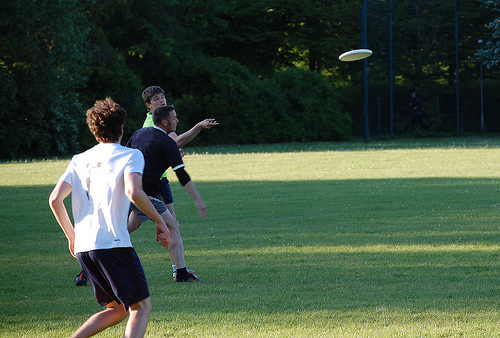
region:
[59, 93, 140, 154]
the head of a man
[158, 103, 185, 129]
the face of a man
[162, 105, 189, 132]
the nose of a man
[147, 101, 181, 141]
the ear of a man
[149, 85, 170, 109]
the eyes of a man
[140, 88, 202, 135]
the hair of a man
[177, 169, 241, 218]
the hand of a man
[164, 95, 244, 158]
the arm of a man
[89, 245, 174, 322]
the legs of a man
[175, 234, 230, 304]
the foot of a man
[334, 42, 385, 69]
A Frisbee flying through the air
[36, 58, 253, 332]
Grown men playing with a Frisbee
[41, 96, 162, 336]
A man in a white shirt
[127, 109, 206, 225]
A black man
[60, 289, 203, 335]
White legs of a man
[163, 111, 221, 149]
A man's arm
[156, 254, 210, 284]
A man's shoe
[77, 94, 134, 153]
Curly hair on the head of a man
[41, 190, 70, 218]
A man's left elbow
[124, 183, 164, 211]
A man's right elbow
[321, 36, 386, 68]
a frisbee flying into the air.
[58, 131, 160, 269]
a man in a white t shirt.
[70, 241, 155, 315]
a man wearing dark shorts.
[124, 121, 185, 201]
a man in a mostly black shirt.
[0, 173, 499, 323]
a shadow cast on a field.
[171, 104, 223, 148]
a right human hand.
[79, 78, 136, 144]
a man with a head of hair.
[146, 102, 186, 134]
a man with short hair.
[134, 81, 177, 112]
a man looking up.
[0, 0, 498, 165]
a forest behind a park.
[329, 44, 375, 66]
The white frisbee.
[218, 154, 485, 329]
The large green grassy field.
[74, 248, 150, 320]
Blue nylon shorts.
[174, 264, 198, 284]
The right black sneaker.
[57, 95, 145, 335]
The boy in a white shirt.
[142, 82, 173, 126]
The boy in the green shirt.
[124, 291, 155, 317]
A right knee.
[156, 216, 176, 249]
The boy in whites right hand.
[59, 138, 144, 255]
The boy in whites shirt.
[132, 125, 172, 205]
The black shirt.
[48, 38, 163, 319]
this is a man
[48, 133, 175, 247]
man wearing white shirt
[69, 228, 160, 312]
man wearing black shorts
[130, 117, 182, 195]
man wearing a black shirt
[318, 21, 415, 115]
this is a frisbee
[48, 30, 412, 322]
group of people playing with a frisbee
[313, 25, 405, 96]
the frisbee is white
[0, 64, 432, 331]
people playing in field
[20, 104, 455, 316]
the field is green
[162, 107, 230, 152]
man has arm extended